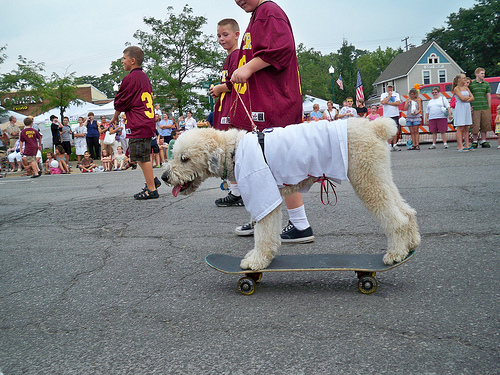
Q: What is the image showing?
A: It is showing a road.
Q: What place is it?
A: It is a road.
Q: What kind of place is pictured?
A: It is a road.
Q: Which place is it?
A: It is a road.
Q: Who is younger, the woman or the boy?
A: The boy is younger than the woman.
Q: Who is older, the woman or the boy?
A: The woman is older than the boy.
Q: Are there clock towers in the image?
A: No, there are no clock towers.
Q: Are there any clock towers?
A: No, there are no clock towers.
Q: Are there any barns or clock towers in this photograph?
A: No, there are no clock towers or barns.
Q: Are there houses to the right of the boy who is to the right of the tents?
A: Yes, there is a house to the right of the boy.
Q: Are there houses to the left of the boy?
A: No, the house is to the right of the boy.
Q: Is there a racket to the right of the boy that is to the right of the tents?
A: No, there is a house to the right of the boy.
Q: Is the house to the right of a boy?
A: Yes, the house is to the right of a boy.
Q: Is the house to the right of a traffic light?
A: No, the house is to the right of a boy.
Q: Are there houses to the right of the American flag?
A: Yes, there is a house to the right of the American flag.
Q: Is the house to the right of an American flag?
A: Yes, the house is to the right of an American flag.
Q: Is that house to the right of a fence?
A: No, the house is to the right of an American flag.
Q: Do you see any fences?
A: No, there are no fences.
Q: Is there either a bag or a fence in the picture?
A: No, there are no fences or bags.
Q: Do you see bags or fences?
A: No, there are no fences or bags.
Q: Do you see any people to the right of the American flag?
A: Yes, there is a person to the right of the American flag.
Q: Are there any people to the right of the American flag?
A: Yes, there is a person to the right of the American flag.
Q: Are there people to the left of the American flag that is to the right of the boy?
A: No, the person is to the right of the American flag.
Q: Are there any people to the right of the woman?
A: Yes, there is a person to the right of the woman.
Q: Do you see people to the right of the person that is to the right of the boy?
A: Yes, there is a person to the right of the woman.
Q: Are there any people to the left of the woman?
A: No, the person is to the right of the woman.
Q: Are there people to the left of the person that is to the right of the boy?
A: No, the person is to the right of the woman.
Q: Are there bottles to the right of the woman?
A: No, there is a person to the right of the woman.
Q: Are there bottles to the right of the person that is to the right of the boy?
A: No, there is a person to the right of the woman.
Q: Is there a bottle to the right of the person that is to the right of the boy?
A: No, there is a person to the right of the woman.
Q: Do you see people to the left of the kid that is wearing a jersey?
A: Yes, there is a person to the left of the kid.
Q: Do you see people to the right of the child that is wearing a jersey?
A: No, the person is to the left of the kid.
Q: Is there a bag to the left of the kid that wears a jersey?
A: No, there is a person to the left of the kid.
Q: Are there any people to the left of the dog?
A: Yes, there is a person to the left of the dog.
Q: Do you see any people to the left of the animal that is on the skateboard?
A: Yes, there is a person to the left of the dog.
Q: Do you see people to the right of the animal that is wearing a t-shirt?
A: No, the person is to the left of the dog.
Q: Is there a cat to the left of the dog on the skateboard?
A: No, there is a person to the left of the dog.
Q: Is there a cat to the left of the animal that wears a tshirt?
A: No, there is a person to the left of the dog.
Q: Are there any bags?
A: No, there are no bags.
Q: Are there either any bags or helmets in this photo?
A: No, there are no bags or helmets.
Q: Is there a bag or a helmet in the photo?
A: No, there are no bags or helmets.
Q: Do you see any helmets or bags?
A: No, there are no bags or helmets.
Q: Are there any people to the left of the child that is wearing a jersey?
A: Yes, there is a person to the left of the kid.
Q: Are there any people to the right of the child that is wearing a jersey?
A: No, the person is to the left of the child.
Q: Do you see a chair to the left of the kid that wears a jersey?
A: No, there is a person to the left of the kid.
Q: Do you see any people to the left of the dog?
A: Yes, there is a person to the left of the dog.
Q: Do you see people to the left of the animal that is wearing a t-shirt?
A: Yes, there is a person to the left of the dog.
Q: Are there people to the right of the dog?
A: No, the person is to the left of the dog.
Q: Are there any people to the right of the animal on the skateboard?
A: No, the person is to the left of the dog.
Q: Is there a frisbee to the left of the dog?
A: No, there is a person to the left of the dog.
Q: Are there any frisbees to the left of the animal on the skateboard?
A: No, there is a person to the left of the dog.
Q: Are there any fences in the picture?
A: No, there are no fences.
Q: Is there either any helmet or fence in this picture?
A: No, there are no fences or helmets.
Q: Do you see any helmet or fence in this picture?
A: No, there are no fences or helmets.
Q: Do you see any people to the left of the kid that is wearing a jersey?
A: Yes, there is a person to the left of the kid.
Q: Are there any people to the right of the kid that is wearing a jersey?
A: No, the person is to the left of the kid.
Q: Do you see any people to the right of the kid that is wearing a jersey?
A: No, the person is to the left of the kid.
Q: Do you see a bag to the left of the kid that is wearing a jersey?
A: No, there is a person to the left of the kid.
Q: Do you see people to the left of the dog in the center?
A: Yes, there is a person to the left of the dog.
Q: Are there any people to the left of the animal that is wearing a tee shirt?
A: Yes, there is a person to the left of the dog.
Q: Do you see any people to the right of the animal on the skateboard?
A: No, the person is to the left of the dog.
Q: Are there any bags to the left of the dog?
A: No, there is a person to the left of the dog.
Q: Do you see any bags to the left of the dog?
A: No, there is a person to the left of the dog.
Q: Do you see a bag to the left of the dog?
A: No, there is a person to the left of the dog.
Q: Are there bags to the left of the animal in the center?
A: No, there is a person to the left of the dog.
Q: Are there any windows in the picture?
A: Yes, there are windows.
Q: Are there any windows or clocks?
A: Yes, there are windows.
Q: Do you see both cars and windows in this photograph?
A: No, there are windows but no cars.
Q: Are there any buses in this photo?
A: No, there are no buses.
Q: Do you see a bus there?
A: No, there are no buses.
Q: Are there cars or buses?
A: No, there are no buses or cars.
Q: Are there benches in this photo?
A: No, there are no benches.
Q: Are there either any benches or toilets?
A: No, there are no benches or toilets.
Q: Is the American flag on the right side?
A: Yes, the American flag is on the right of the image.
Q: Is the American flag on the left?
A: No, the American flag is on the right of the image.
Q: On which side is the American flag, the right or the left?
A: The American flag is on the right of the image.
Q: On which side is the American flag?
A: The American flag is on the right of the image.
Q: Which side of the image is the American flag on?
A: The American flag is on the right of the image.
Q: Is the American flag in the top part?
A: Yes, the American flag is in the top of the image.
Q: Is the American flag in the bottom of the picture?
A: No, the American flag is in the top of the image.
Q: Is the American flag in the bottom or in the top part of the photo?
A: The American flag is in the top of the image.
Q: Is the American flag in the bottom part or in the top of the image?
A: The American flag is in the top of the image.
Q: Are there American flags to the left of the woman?
A: Yes, there is an American flag to the left of the woman.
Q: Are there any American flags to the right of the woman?
A: No, the American flag is to the left of the woman.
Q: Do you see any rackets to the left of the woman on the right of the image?
A: No, there is an American flag to the left of the woman.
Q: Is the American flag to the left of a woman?
A: Yes, the American flag is to the left of a woman.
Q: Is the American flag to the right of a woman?
A: No, the American flag is to the left of a woman.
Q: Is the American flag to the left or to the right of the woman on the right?
A: The American flag is to the left of the woman.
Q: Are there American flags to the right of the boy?
A: Yes, there is an American flag to the right of the boy.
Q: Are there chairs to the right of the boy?
A: No, there is an American flag to the right of the boy.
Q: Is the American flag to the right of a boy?
A: Yes, the American flag is to the right of a boy.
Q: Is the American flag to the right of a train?
A: No, the American flag is to the right of a boy.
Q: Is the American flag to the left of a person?
A: Yes, the American flag is to the left of a person.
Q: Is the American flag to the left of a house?
A: Yes, the American flag is to the left of a house.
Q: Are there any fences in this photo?
A: No, there are no fences.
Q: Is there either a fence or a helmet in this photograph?
A: No, there are no fences or helmets.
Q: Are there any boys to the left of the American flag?
A: Yes, there is a boy to the left of the American flag.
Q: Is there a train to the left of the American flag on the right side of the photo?
A: No, there is a boy to the left of the American flag.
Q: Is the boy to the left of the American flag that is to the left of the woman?
A: Yes, the boy is to the left of the American flag.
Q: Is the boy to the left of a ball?
A: No, the boy is to the left of the American flag.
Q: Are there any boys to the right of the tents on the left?
A: Yes, there is a boy to the right of the tents.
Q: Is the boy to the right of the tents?
A: Yes, the boy is to the right of the tents.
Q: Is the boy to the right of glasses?
A: No, the boy is to the right of the tents.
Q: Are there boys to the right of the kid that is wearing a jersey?
A: Yes, there is a boy to the right of the child.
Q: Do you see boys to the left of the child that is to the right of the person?
A: No, the boy is to the right of the kid.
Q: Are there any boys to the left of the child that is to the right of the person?
A: No, the boy is to the right of the kid.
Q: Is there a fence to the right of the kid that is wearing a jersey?
A: No, there is a boy to the right of the kid.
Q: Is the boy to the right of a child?
A: Yes, the boy is to the right of a child.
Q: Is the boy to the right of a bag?
A: No, the boy is to the right of a child.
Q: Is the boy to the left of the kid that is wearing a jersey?
A: No, the boy is to the right of the child.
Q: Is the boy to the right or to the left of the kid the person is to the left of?
A: The boy is to the right of the kid.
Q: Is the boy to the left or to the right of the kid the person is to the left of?
A: The boy is to the right of the kid.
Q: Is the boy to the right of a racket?
A: No, the boy is to the right of a child.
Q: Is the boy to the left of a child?
A: No, the boy is to the right of a child.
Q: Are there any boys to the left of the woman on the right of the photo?
A: Yes, there is a boy to the left of the woman.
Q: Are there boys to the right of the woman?
A: No, the boy is to the left of the woman.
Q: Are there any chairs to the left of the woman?
A: No, there is a boy to the left of the woman.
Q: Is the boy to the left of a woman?
A: Yes, the boy is to the left of a woman.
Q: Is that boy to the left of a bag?
A: No, the boy is to the left of a woman.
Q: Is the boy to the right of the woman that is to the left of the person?
A: No, the boy is to the left of the woman.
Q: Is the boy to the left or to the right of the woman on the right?
A: The boy is to the left of the woman.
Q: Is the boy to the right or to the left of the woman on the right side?
A: The boy is to the left of the woman.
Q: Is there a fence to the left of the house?
A: No, there is a boy to the left of the house.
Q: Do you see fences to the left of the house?
A: No, there is a boy to the left of the house.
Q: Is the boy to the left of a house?
A: Yes, the boy is to the left of a house.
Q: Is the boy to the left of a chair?
A: No, the boy is to the left of a house.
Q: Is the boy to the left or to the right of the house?
A: The boy is to the left of the house.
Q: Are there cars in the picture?
A: No, there are no cars.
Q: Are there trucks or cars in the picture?
A: No, there are no cars or trucks.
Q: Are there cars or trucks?
A: No, there are no cars or trucks.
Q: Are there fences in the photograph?
A: No, there are no fences.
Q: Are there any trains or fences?
A: No, there are no fences or trains.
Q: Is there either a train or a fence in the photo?
A: No, there are no fences or trains.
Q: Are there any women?
A: Yes, there is a woman.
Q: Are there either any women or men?
A: Yes, there is a woman.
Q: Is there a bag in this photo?
A: No, there are no bags.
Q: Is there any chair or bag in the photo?
A: No, there are no bags or chairs.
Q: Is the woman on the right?
A: Yes, the woman is on the right of the image.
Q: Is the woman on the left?
A: No, the woman is on the right of the image.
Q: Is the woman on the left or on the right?
A: The woman is on the right of the image.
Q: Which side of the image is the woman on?
A: The woman is on the right of the image.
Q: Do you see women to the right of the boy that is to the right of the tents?
A: Yes, there is a woman to the right of the boy.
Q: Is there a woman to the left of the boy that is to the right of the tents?
A: No, the woman is to the right of the boy.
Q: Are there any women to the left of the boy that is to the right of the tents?
A: No, the woman is to the right of the boy.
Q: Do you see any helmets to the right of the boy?
A: No, there is a woman to the right of the boy.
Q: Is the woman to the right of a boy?
A: Yes, the woman is to the right of a boy.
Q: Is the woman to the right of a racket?
A: No, the woman is to the right of a boy.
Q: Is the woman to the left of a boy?
A: No, the woman is to the right of a boy.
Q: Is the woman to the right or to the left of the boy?
A: The woman is to the right of the boy.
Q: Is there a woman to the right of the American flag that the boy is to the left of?
A: Yes, there is a woman to the right of the American flag.